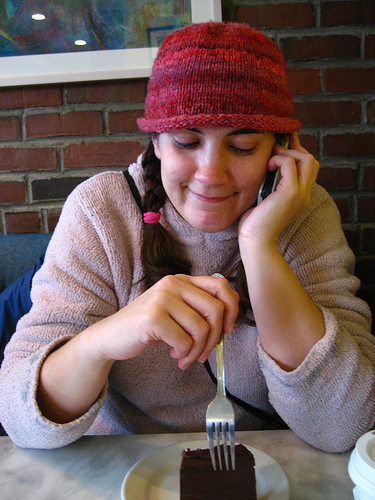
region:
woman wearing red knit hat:
[134, 21, 301, 132]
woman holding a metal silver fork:
[205, 271, 239, 471]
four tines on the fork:
[228, 423, 237, 470]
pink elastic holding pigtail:
[142, 211, 162, 225]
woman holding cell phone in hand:
[256, 131, 302, 202]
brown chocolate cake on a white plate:
[180, 444, 255, 498]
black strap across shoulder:
[120, 168, 144, 213]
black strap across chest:
[204, 360, 288, 428]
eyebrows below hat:
[226, 126, 265, 137]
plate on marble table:
[122, 438, 288, 498]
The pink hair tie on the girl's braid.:
[138, 205, 164, 224]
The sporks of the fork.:
[203, 420, 238, 468]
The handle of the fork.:
[206, 274, 232, 384]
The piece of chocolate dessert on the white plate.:
[181, 446, 252, 499]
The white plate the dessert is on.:
[113, 441, 294, 498]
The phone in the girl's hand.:
[260, 129, 291, 203]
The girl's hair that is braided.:
[143, 140, 164, 210]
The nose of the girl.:
[192, 162, 228, 185]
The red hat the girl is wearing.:
[137, 23, 304, 131]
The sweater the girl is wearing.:
[1, 159, 373, 455]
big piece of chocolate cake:
[173, 432, 259, 498]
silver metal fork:
[183, 272, 244, 486]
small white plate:
[110, 429, 296, 497]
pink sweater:
[9, 166, 370, 460]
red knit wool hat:
[128, 20, 308, 140]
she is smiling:
[111, 23, 315, 310]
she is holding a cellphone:
[234, 120, 326, 221]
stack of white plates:
[336, 416, 372, 496]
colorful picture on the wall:
[2, 6, 223, 92]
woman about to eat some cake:
[2, 2, 366, 453]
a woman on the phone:
[105, 40, 368, 313]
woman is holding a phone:
[131, 42, 337, 292]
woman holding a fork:
[106, 242, 274, 498]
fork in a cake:
[145, 302, 277, 496]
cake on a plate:
[142, 422, 252, 493]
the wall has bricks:
[26, 87, 139, 206]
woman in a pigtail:
[138, 136, 323, 339]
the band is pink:
[128, 206, 169, 236]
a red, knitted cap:
[131, 6, 307, 168]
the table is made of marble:
[33, 443, 105, 496]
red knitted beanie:
[135, 21, 300, 134]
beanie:
[134, 20, 300, 130]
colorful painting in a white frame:
[1, 0, 222, 86]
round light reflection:
[29, 9, 47, 21]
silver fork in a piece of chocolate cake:
[180, 334, 257, 497]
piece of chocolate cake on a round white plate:
[121, 436, 290, 499]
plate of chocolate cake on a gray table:
[1, 430, 352, 497]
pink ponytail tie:
[141, 210, 160, 225]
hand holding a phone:
[241, 132, 320, 233]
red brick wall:
[0, 83, 136, 172]